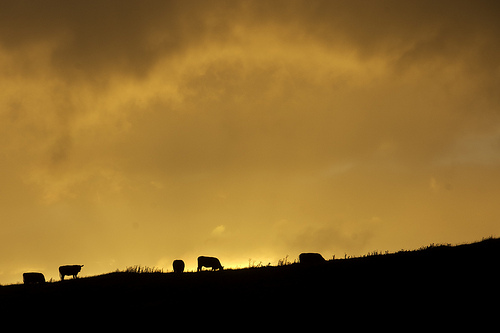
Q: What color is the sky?
A: Orange.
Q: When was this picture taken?
A: Sunset.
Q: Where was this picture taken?
A: Outside in field.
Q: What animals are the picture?
A: Cows.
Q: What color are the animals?
A: Black.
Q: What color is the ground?
A: Black.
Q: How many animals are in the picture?
A: Five.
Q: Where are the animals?
A: On a hill.